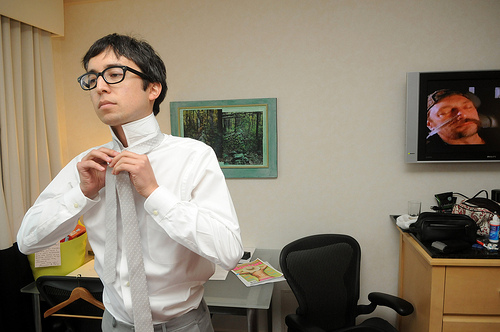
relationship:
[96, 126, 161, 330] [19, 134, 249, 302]
grey tie on shirt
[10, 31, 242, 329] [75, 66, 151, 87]
boy has on glasses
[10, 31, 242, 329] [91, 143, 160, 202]
boy has hand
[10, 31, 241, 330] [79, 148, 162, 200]
boy has hand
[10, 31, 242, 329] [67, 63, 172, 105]
boy wears glasses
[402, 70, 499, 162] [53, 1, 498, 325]
television on wall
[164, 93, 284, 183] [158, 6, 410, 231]
picture on wall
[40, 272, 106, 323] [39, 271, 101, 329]
coat hanger on chair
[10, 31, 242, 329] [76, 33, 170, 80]
boy has hair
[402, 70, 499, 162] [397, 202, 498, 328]
television above cabinet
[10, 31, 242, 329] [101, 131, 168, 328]
boy ties tie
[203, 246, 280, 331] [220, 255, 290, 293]
table has magazine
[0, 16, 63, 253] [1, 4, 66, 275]
curtains on window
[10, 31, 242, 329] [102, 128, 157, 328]
boy wears tie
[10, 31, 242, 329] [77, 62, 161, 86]
boy wears glasses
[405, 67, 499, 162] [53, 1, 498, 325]
screen on wall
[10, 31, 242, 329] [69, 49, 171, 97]
boy wears glasses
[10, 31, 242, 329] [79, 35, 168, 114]
boy has black hair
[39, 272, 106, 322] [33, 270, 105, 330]
coat hanger on chair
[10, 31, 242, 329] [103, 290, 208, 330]
boy wears bottoms